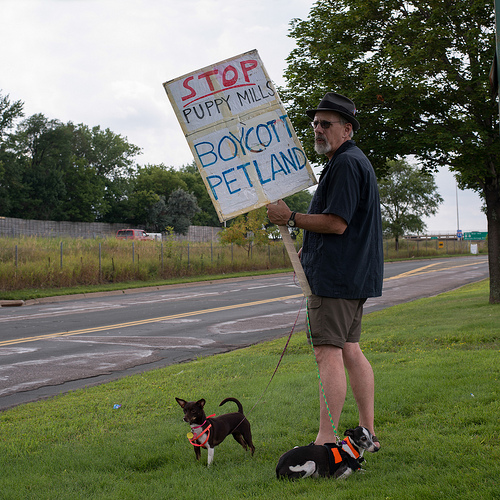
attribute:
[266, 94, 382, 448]
man — protesting, standing, boycotting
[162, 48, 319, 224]
sign — homemade, for protestig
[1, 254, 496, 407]
road — black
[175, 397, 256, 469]
chihuahua — white, brown, alert, looking, black, standing, small, standing up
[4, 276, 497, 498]
grass — short, green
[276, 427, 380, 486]
dog — laying, white, black, sitting, small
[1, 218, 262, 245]
fence — made of wood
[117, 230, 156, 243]
truck — red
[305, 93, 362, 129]
hat — old style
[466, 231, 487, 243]
road sign — green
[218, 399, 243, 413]
puppy's tail — black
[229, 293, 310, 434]
leash — red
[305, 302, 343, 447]
leash — orange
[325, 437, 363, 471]
harness — orange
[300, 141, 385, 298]
shirt — black, short sleeve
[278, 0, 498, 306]
tree — big